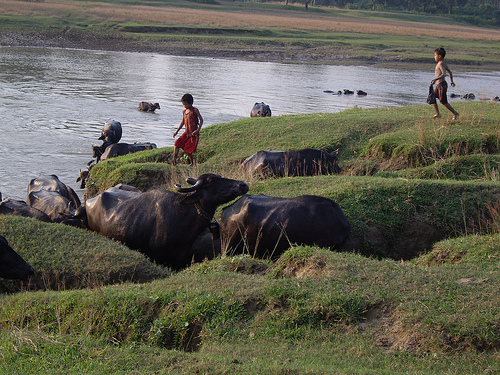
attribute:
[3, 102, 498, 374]
grass — tall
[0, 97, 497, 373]
hillside — grassy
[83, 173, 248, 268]
water buffalo — black 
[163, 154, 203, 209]
horns — brown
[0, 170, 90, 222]
hippo — black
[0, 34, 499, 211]
water — clear, calm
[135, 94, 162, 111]
mammal — lone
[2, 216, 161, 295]
grass — in distance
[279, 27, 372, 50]
grass — flat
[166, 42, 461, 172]
children — short, native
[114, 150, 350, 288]
buffalo — water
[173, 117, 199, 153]
clothing — red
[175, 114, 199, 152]
outfit — red